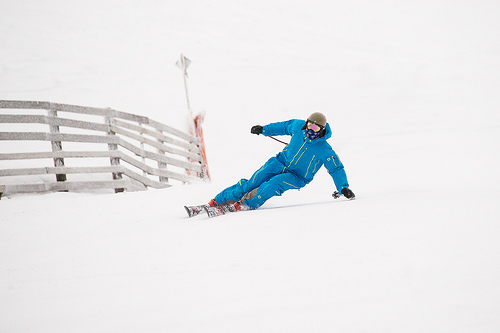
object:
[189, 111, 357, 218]
man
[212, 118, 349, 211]
suit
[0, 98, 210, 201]
fence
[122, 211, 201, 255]
snow